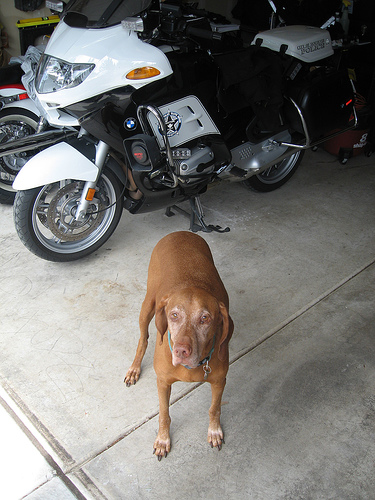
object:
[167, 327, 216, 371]
blue collar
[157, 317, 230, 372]
neck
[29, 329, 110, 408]
thin marks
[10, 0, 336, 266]
motorcycle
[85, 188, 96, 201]
orange reflector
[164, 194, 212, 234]
kickstand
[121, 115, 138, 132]
logo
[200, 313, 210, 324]
eyes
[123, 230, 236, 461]
dog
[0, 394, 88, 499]
black strip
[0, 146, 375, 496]
concrete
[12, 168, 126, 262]
wheel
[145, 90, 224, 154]
motor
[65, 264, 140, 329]
spot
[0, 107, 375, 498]
ground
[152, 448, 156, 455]
nails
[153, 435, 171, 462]
paw